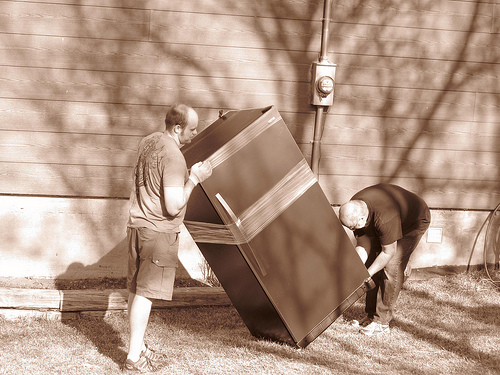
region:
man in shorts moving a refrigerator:
[122, 102, 369, 372]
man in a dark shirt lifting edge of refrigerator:
[176, 102, 426, 347]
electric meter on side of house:
[310, 60, 335, 105]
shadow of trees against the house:
[5, 1, 495, 262]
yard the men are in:
[1, 262, 496, 372]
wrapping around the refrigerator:
[185, 156, 317, 241]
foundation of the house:
[0, 197, 496, 273]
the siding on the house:
[1, 0, 496, 210]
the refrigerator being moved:
[178, 108, 374, 348]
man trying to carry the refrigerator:
[99, 68, 447, 339]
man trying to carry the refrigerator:
[81, 72, 455, 359]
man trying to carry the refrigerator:
[55, 83, 439, 362]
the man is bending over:
[302, 148, 432, 333]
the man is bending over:
[305, 150, 440, 336]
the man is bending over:
[301, 149, 469, 360]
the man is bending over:
[301, 148, 452, 362]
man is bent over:
[338, 166, 425, 276]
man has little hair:
[336, 188, 380, 234]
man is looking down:
[332, 199, 394, 256]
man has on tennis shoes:
[363, 297, 388, 342]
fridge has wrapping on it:
[175, 168, 314, 290]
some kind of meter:
[304, 49, 356, 137]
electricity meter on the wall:
[292, 45, 346, 108]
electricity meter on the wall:
[292, 42, 357, 108]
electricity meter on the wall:
[295, 53, 355, 118]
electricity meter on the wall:
[298, 40, 360, 124]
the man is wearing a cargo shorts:
[99, 210, 199, 305]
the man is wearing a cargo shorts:
[96, 206, 187, 328]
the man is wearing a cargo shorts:
[114, 198, 190, 332]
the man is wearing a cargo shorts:
[108, 185, 185, 314]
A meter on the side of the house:
[311, 61, 337, 109]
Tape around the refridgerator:
[186, 160, 317, 242]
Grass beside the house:
[0, 263, 496, 373]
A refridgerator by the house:
[180, 108, 375, 348]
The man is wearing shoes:
[123, 344, 169, 373]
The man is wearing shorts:
[121, 225, 180, 302]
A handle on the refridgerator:
[215, 193, 267, 275]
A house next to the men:
[0, 1, 497, 318]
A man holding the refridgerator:
[120, 103, 210, 372]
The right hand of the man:
[190, 158, 217, 180]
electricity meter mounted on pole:
[308, 56, 340, 111]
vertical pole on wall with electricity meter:
[311, 14, 333, 186]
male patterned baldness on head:
[170, 98, 202, 126]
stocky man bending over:
[338, 171, 434, 339]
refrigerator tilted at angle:
[173, 92, 376, 353]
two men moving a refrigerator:
[112, 90, 427, 373]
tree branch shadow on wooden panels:
[375, 21, 492, 176]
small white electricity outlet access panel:
[426, 224, 443, 244]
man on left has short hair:
[158, 91, 203, 138]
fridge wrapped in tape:
[190, 166, 292, 279]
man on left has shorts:
[114, 218, 175, 304]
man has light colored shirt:
[120, 133, 177, 246]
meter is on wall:
[312, 23, 353, 103]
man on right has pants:
[379, 251, 413, 316]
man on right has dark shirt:
[346, 172, 413, 239]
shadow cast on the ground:
[188, 317, 340, 362]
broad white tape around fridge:
[231, 175, 336, 232]